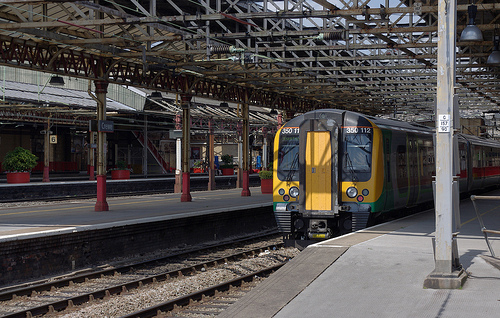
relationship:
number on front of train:
[345, 126, 351, 135] [268, 102, 499, 244]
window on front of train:
[275, 131, 302, 182] [268, 102, 499, 244]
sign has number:
[46, 134, 59, 146] [49, 135, 57, 142]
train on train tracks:
[268, 102, 499, 244] [3, 229, 301, 318]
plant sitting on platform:
[257, 166, 279, 195] [0, 178, 280, 276]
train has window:
[268, 102, 499, 244] [275, 131, 302, 182]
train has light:
[268, 102, 499, 244] [354, 194, 366, 203]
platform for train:
[0, 178, 280, 276] [268, 102, 499, 244]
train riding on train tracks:
[268, 102, 499, 244] [3, 229, 301, 318]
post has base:
[89, 69, 111, 219] [90, 172, 111, 215]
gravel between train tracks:
[0, 246, 290, 318] [3, 229, 301, 318]